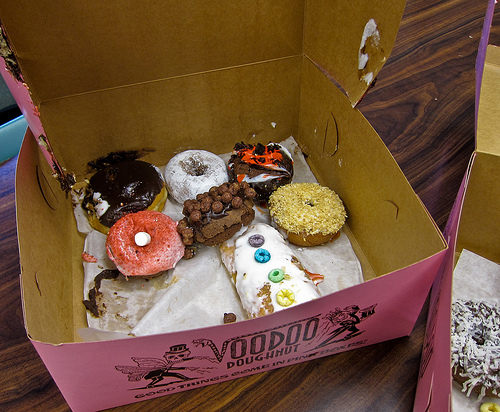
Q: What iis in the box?
A: Doughnuts.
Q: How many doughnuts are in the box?
A: Seven.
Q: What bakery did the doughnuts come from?
A: Voodoo.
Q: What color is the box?
A: Pink.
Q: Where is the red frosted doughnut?
A: In the box.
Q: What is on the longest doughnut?
A: Fruit Loops.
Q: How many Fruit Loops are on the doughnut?
A: Four.